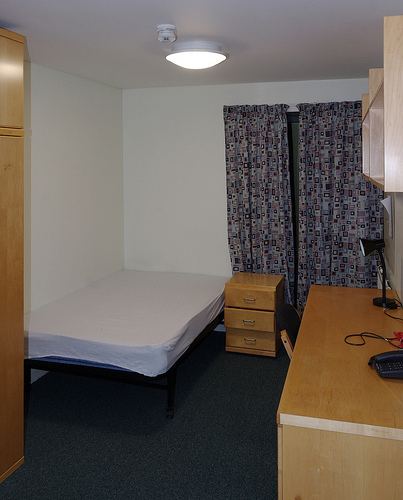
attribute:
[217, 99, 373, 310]
curtains — patterned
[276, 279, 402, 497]
desk — brown, wooden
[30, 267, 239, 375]
sheet — white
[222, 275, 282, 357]
cabinet — wooden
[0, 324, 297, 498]
carpet — dark colored, blue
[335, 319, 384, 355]
cord — black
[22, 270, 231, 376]
sheet — white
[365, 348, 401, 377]
phone — black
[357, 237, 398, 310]
lamp — small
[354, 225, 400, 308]
lamp — small, black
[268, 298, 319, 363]
chair — black and brown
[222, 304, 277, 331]
drawers — black and brown, open